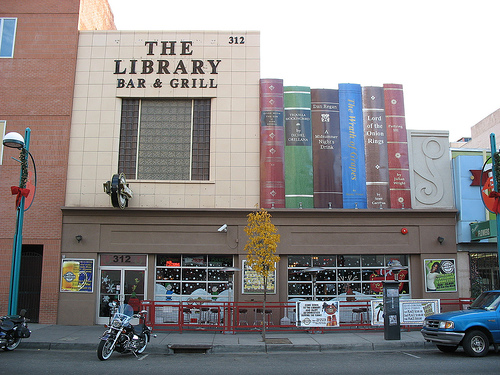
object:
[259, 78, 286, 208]
book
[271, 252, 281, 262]
leaf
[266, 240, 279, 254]
leaf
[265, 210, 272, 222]
leaf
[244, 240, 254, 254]
leaf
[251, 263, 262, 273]
leaf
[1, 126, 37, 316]
pole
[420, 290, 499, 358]
blue truck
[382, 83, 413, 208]
book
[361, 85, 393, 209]
book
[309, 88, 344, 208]
book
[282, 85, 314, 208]
book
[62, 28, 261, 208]
wall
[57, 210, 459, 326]
wall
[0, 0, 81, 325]
wall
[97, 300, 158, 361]
motorcycle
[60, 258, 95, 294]
poster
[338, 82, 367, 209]
book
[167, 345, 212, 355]
drain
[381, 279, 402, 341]
meter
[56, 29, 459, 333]
building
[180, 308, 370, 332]
stools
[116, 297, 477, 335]
outdoor counter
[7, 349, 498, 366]
road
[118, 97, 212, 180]
window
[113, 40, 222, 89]
name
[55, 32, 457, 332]
establishment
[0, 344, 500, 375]
pavement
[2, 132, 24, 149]
street light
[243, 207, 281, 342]
leaves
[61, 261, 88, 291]
mug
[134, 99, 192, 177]
tiles